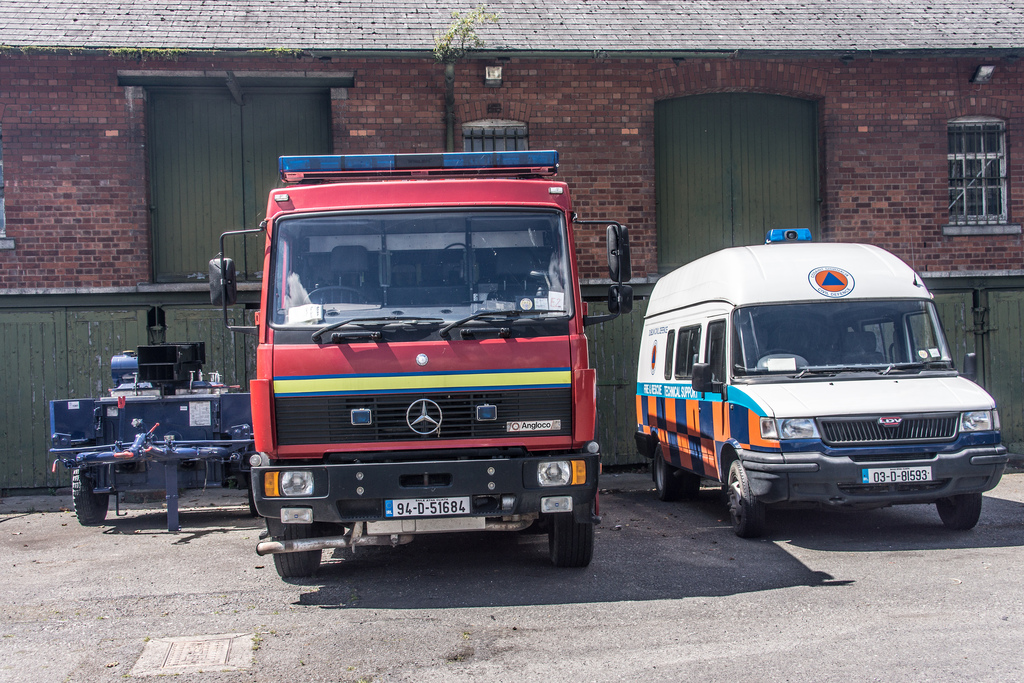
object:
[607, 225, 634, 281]
mirror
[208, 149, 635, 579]
bus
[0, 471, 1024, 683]
pavement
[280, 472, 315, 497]
light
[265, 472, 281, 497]
light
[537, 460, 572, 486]
light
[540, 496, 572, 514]
light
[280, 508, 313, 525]
light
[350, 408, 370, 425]
light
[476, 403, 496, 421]
light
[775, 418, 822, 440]
light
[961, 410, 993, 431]
light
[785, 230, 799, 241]
light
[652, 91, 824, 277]
doors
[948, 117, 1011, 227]
bars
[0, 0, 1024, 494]
building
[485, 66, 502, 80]
light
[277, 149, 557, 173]
light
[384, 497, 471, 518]
plate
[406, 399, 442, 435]
brand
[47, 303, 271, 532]
trailer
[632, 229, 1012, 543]
car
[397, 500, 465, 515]
lettering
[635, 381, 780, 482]
stripes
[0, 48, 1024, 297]
wall